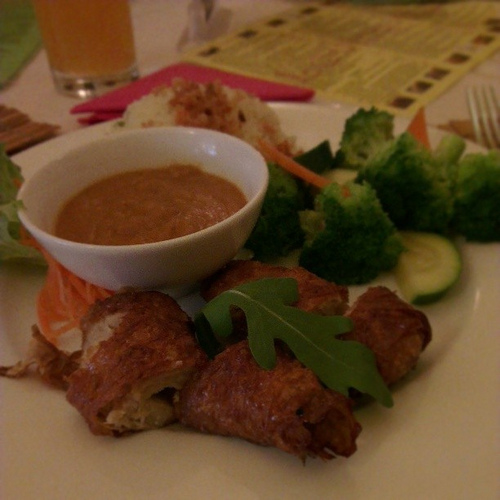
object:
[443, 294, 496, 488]
plate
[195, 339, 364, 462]
food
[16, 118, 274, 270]
bowl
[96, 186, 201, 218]
dip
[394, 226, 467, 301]
cucumber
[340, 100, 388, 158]
vegetables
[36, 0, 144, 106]
glass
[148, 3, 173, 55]
table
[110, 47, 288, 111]
napkin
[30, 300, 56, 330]
carrots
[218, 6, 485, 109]
menu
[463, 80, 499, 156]
fork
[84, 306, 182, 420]
dough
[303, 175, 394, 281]
broccoli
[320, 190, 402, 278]
head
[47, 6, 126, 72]
beverage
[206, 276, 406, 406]
leaf